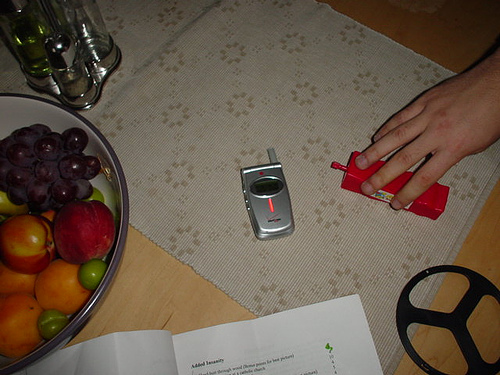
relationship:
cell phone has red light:
[240, 148, 295, 242] [264, 187, 276, 215]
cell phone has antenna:
[237, 144, 294, 242] [267, 150, 282, 167]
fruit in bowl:
[0, 120, 121, 359] [23, 89, 220, 369]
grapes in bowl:
[0, 121, 103, 214] [4, 85, 139, 374]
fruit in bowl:
[0, 120, 121, 359] [4, 85, 139, 374]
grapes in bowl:
[2, 119, 101, 209] [4, 85, 139, 374]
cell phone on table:
[240, 148, 295, 242] [0, 2, 500, 374]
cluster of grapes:
[12, 117, 122, 221] [0, 120, 105, 213]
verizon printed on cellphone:
[251, 212, 292, 232] [239, 147, 294, 241]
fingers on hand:
[355, 91, 461, 210] [348, 50, 498, 215]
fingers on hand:
[386, 155, 447, 222] [348, 50, 498, 215]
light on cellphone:
[262, 196, 281, 217] [226, 162, 318, 246]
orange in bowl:
[33, 260, 92, 317] [0, 90, 124, 367]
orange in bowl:
[1, 262, 36, 293] [0, 90, 124, 367]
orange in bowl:
[1, 292, 48, 355] [0, 90, 124, 367]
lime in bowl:
[83, 256, 106, 283] [0, 78, 130, 372]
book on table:
[15, 290, 393, 373] [0, 2, 500, 374]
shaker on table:
[29, 23, 99, 104] [105, 0, 493, 365]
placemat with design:
[1, 0, 496, 374] [221, 83, 257, 123]